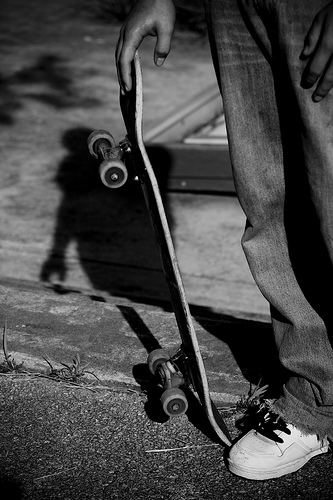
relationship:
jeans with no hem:
[201, 4, 331, 432] [287, 416, 311, 432]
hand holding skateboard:
[114, 0, 175, 94] [91, 47, 238, 445]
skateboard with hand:
[91, 47, 238, 445] [100, 1, 193, 96]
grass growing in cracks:
[3, 321, 89, 395] [7, 349, 148, 398]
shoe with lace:
[227, 411, 329, 481] [248, 410, 290, 447]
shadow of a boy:
[40, 126, 284, 399] [113, 4, 332, 487]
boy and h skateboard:
[113, 4, 332, 487] [41, 39, 236, 460]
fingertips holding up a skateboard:
[120, 65, 131, 92] [91, 47, 238, 445]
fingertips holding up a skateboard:
[117, 80, 127, 96] [91, 47, 238, 445]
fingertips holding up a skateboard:
[153, 48, 169, 66] [91, 47, 238, 445]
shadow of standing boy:
[33, 122, 173, 404] [115, 0, 333, 482]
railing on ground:
[117, 73, 246, 203] [3, 2, 331, 267]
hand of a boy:
[114, 0, 175, 94] [115, 0, 333, 482]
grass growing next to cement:
[0, 317, 269, 407] [5, 369, 328, 496]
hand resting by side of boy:
[295, 11, 332, 98] [115, 0, 333, 482]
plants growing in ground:
[1, 311, 102, 386] [1, 1, 330, 499]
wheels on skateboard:
[84, 124, 129, 187] [91, 47, 238, 445]